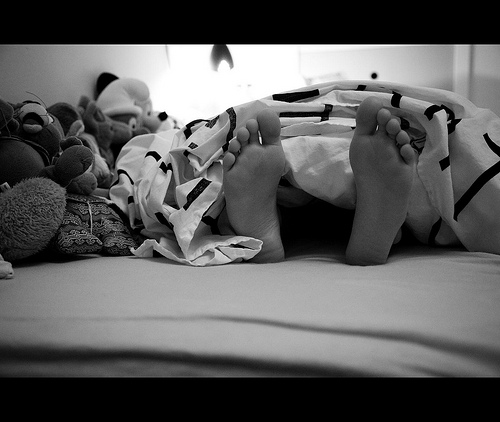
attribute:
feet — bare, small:
[202, 90, 389, 259]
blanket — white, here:
[282, 91, 326, 148]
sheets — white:
[109, 287, 130, 298]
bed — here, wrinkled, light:
[28, 352, 79, 377]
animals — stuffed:
[31, 109, 151, 238]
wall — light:
[48, 63, 65, 69]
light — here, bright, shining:
[163, 69, 183, 84]